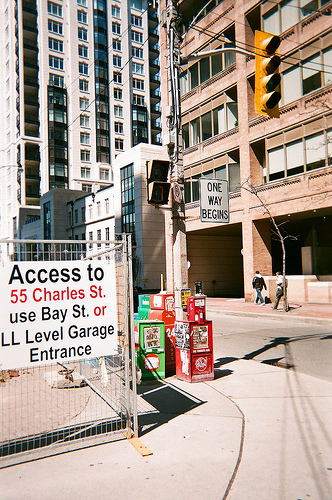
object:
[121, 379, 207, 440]
shadow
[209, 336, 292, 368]
shadow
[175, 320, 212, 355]
metal box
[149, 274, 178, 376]
machine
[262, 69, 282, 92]
stop light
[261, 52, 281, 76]
street light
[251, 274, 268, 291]
jacket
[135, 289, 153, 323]
machines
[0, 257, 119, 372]
sign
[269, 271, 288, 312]
man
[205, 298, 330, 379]
street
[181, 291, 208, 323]
dispenser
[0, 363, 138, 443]
fence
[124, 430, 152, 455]
plank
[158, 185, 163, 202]
7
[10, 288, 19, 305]
number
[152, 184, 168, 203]
number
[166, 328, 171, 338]
number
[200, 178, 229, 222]
sign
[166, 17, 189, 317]
pole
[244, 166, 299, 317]
tree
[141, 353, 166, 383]
green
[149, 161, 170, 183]
light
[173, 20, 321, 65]
wires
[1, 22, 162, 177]
wires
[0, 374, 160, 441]
cement slab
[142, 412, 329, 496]
ground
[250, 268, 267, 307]
man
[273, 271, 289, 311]
walking man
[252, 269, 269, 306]
walking man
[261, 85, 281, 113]
light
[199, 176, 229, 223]
traffic sign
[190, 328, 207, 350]
metal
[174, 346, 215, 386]
box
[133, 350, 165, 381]
box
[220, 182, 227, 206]
white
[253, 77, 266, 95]
yellow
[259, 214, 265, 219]
leaves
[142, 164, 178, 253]
walk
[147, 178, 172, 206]
box